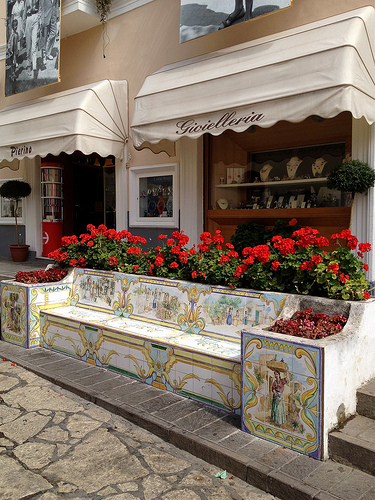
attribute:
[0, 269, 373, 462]
bench — tiled, painted, cement, old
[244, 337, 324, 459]
painting — woman with basket on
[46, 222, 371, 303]
flowers — red, geraniums, blooming, healthy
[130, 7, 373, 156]
awning — white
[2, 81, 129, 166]
awning — white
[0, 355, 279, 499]
street — flagstone, stone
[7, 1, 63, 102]
artwork — monochromatic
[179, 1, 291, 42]
artwork — monochromatic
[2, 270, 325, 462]
tiles — painted